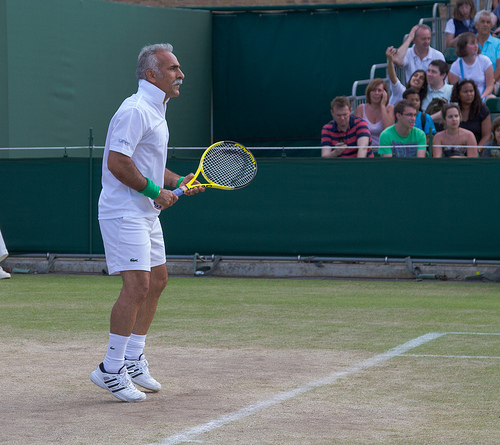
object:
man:
[89, 41, 208, 402]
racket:
[152, 139, 259, 211]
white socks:
[103, 332, 132, 374]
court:
[0, 271, 499, 444]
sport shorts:
[96, 213, 168, 276]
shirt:
[98, 77, 171, 220]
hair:
[135, 41, 173, 82]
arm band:
[136, 177, 161, 198]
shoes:
[88, 360, 149, 404]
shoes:
[122, 356, 162, 394]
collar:
[136, 77, 167, 105]